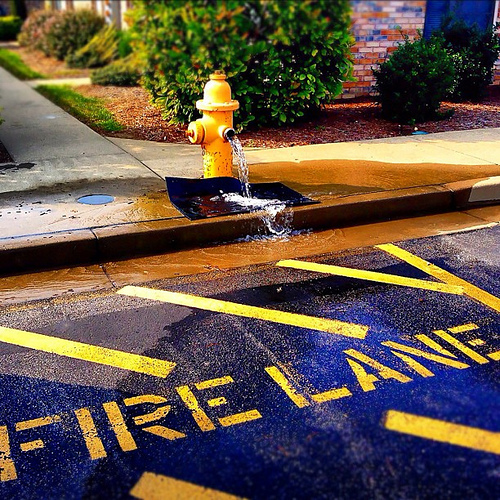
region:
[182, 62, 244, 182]
yellow fire hydrant on sidewalk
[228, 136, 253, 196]
water pouring out of fire hydrant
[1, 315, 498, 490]
yellow words on street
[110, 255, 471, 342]
yellow lines drawn on sidewalk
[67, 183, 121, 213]
metal hole cover on sidewalk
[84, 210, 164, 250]
patch of wet sidewalk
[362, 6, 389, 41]
bricks on side of building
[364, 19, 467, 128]
green bush next to brick building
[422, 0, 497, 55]
black door on side of building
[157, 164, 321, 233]
black mat underneath yellow fire hydrant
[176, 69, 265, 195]
yellow fire hydrant on the sidewalk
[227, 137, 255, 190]
a stream of water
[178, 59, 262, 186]
water coming out of the hydrant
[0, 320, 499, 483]
yellow writing on the road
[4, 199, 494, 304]
water on the curb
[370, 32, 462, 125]
small green bush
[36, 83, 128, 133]
small patch of green grass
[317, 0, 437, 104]
side of a brick building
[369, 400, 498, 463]
yellow line on the ground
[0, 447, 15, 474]
yellow paint is chipping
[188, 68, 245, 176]
Small yellow fire hydrant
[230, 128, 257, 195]
Water running from fire hydrant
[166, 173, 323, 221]
Blue mat on floor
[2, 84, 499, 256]
Pavement made of concrete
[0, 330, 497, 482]
Yellow writings on ground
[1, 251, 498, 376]
Yellow lines on road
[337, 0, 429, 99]
Building made of bricks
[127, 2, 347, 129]
Green bush behind fire hydrant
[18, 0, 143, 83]
Plants growing beside building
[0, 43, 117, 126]
Green grass beside pavement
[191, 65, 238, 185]
this is a hydrant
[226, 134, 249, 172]
this is the water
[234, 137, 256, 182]
the water is flowing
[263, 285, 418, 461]
this is the road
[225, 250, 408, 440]
the road is wet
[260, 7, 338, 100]
these are the leaves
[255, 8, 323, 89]
the leaves are green in color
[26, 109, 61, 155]
this is a pavement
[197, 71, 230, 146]
the hydrant is yellow in color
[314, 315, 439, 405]
yellow strips are on the road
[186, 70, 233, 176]
The fire hydrant is yellow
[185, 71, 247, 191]
Water coming out of the fire hydrant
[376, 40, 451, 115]
The bush is colored green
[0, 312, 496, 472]
The ground says fire lane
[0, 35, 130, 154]
There are small bushes for the sidewalk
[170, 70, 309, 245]
The water is overflowing onto the ground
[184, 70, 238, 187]
The sun is shining on the left side of the hydrant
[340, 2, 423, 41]
Different colored bricks on the wall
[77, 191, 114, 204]
A silver sewer lid on the ground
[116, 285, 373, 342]
The fire lane line is diagonal